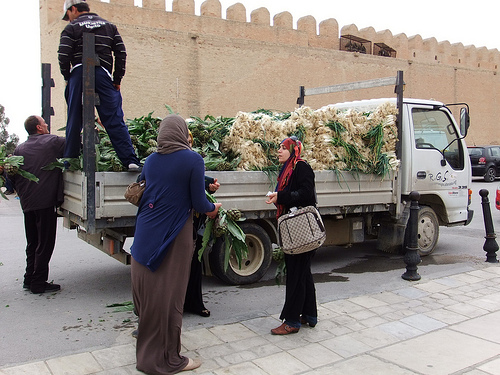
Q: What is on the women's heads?
A: Head scarf.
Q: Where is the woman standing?
A: Near street.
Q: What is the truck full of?
A: Plants.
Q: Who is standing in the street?
A: A woman.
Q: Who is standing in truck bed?
A: A man.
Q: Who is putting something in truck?
A: A man.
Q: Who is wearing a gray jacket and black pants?
A: Man behind truck.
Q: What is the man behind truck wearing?
A: Dark pants.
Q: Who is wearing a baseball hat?
A: Man on top truck.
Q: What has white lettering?
A: Black jacket.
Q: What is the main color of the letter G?
A: Black.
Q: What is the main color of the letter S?
A: Black.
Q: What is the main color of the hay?
A: Brown.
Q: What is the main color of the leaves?
A: Green.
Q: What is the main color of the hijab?
A: Red.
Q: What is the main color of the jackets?
A: Black.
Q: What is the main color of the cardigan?
A: Blue.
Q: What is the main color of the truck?
A: White.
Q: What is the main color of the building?
A: Brown.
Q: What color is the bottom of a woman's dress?
A: Brown.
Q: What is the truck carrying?
A: A supply of plants.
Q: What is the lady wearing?
A: A blue coat.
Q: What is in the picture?
A: Passenger door of truck.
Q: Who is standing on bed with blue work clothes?
A: A man.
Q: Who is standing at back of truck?
A: A man.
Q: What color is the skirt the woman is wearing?
A: Gray.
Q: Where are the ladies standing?
A: At the sidewalk.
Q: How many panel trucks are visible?
A: One.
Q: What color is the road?
A: Grey.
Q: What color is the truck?
A: White.